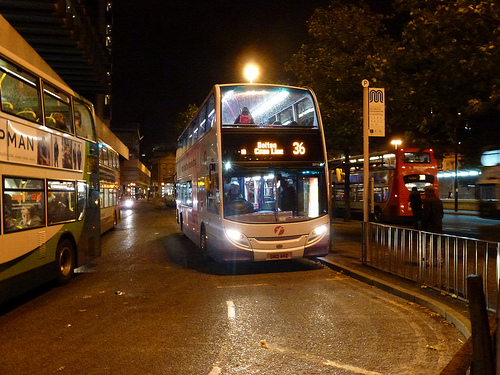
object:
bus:
[326, 147, 442, 222]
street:
[0, 201, 474, 375]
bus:
[0, 47, 103, 284]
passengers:
[18, 202, 45, 227]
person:
[231, 105, 256, 128]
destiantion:
[254, 141, 286, 155]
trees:
[274, 1, 500, 224]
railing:
[359, 219, 498, 314]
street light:
[239, 61, 261, 83]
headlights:
[223, 227, 249, 244]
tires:
[55, 231, 77, 282]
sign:
[366, 86, 386, 138]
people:
[420, 185, 445, 267]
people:
[406, 184, 422, 229]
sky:
[0, 1, 325, 161]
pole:
[361, 85, 372, 266]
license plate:
[266, 249, 295, 261]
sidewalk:
[443, 208, 483, 217]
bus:
[172, 82, 332, 264]